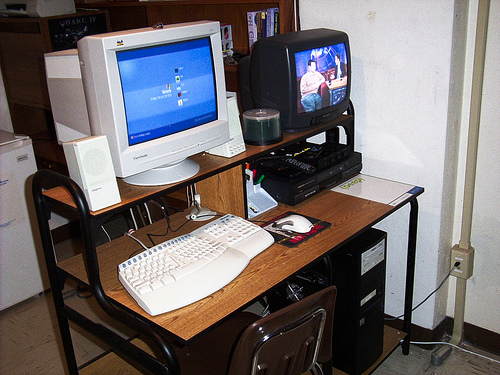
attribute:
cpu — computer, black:
[257, 225, 386, 372]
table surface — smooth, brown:
[320, 192, 383, 219]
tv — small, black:
[247, 25, 354, 130]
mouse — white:
[225, 213, 327, 255]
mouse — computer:
[272, 211, 313, 241]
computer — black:
[326, 229, 410, 369]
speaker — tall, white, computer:
[60, 132, 124, 212]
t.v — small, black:
[259, 36, 354, 132]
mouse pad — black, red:
[256, 210, 331, 250]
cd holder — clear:
[248, 91, 293, 145]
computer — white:
[52, 48, 260, 138]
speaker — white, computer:
[74, 136, 121, 212]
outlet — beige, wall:
[448, 245, 477, 277]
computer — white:
[40, 17, 248, 214]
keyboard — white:
[114, 214, 274, 319]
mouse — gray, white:
[278, 212, 318, 239]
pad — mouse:
[318, 212, 334, 232]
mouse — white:
[273, 214, 313, 235]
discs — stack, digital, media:
[242, 108, 281, 143]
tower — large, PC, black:
[268, 223, 386, 373]